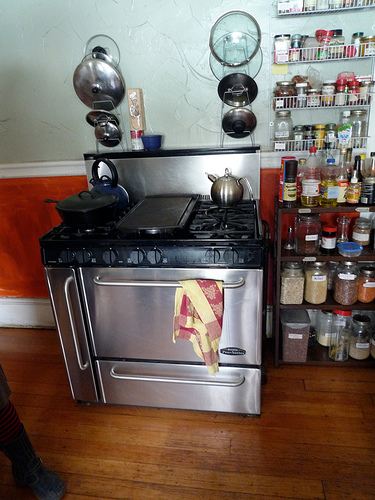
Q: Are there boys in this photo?
A: No, there are no boys.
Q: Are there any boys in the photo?
A: No, there are no boys.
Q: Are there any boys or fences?
A: No, there are no boys or fences.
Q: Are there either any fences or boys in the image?
A: No, there are no boys or fences.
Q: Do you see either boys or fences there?
A: No, there are no boys or fences.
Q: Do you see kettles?
A: Yes, there is a kettle.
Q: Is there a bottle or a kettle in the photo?
A: Yes, there is a kettle.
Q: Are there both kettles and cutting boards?
A: No, there is a kettle but no cutting boards.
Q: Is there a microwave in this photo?
A: No, there are no microwaves.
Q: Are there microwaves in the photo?
A: No, there are no microwaves.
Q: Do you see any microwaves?
A: No, there are no microwaves.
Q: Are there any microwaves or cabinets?
A: No, there are no microwaves or cabinets.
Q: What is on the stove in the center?
A: The kettle is on the stove.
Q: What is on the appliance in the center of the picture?
A: The kettle is on the stove.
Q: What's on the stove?
A: The kettle is on the stove.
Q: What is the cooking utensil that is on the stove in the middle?
A: The cooking utensil is a kettle.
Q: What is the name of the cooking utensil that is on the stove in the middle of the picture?
A: The cooking utensil is a kettle.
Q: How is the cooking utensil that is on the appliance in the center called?
A: The cooking utensil is a kettle.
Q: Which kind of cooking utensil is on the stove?
A: The cooking utensil is a kettle.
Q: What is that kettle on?
A: The kettle is on the stove.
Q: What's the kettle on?
A: The kettle is on the stove.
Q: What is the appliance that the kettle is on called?
A: The appliance is a stove.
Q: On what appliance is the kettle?
A: The kettle is on the stove.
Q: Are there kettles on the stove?
A: Yes, there is a kettle on the stove.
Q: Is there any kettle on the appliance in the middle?
A: Yes, there is a kettle on the stove.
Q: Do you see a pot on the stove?
A: No, there is a kettle on the stove.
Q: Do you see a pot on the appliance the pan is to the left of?
A: No, there is a kettle on the stove.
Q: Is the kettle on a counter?
A: No, the kettle is on the stove.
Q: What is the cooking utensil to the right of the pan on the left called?
A: The cooking utensil is a kettle.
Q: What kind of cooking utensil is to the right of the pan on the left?
A: The cooking utensil is a kettle.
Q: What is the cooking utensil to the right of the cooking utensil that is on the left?
A: The cooking utensil is a kettle.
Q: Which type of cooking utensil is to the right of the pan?
A: The cooking utensil is a kettle.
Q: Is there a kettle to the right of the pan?
A: Yes, there is a kettle to the right of the pan.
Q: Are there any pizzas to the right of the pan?
A: No, there is a kettle to the right of the pan.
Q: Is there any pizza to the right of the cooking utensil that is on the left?
A: No, there is a kettle to the right of the pan.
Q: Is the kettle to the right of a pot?
A: No, the kettle is to the right of a pan.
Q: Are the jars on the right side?
A: Yes, the jars are on the right of the image.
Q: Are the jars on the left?
A: No, the jars are on the right of the image.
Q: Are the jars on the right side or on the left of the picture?
A: The jars are on the right of the image.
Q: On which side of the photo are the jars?
A: The jars are on the right of the image.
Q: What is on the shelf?
A: The jars are on the shelf.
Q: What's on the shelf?
A: The jars are on the shelf.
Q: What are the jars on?
A: The jars are on the shelf.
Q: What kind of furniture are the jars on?
A: The jars are on the shelf.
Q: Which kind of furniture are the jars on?
A: The jars are on the shelf.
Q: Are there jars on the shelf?
A: Yes, there are jars on the shelf.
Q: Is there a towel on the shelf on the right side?
A: No, there are jars on the shelf.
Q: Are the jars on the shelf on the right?
A: Yes, the jars are on the shelf.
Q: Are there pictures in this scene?
A: No, there are no pictures.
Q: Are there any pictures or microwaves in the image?
A: No, there are no pictures or microwaves.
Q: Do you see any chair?
A: No, there are no chairs.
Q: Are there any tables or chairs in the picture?
A: No, there are no chairs or tables.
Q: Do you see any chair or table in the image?
A: No, there are no chairs or tables.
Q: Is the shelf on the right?
A: Yes, the shelf is on the right of the image.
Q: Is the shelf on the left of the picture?
A: No, the shelf is on the right of the image.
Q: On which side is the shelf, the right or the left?
A: The shelf is on the right of the image.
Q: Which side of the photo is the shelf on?
A: The shelf is on the right of the image.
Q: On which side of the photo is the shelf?
A: The shelf is on the right of the image.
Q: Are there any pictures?
A: No, there are no pictures.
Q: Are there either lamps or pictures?
A: No, there are no pictures or lamps.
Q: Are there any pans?
A: Yes, there is a pan.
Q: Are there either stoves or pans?
A: Yes, there is a pan.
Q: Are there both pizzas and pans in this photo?
A: No, there is a pan but no pizzas.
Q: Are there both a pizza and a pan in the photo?
A: No, there is a pan but no pizzas.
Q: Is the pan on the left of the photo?
A: Yes, the pan is on the left of the image.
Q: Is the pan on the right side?
A: No, the pan is on the left of the image.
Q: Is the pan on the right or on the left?
A: The pan is on the left of the image.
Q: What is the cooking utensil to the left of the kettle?
A: The cooking utensil is a pan.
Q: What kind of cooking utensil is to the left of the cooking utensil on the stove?
A: The cooking utensil is a pan.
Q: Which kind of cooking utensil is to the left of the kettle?
A: The cooking utensil is a pan.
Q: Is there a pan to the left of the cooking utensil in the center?
A: Yes, there is a pan to the left of the kettle.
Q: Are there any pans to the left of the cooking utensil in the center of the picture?
A: Yes, there is a pan to the left of the kettle.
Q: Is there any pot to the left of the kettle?
A: No, there is a pan to the left of the kettle.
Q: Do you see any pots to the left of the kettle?
A: No, there is a pan to the left of the kettle.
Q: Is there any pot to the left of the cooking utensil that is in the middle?
A: No, there is a pan to the left of the kettle.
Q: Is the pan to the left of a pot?
A: No, the pan is to the left of a kettle.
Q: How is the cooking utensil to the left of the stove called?
A: The cooking utensil is a pan.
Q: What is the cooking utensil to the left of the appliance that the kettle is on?
A: The cooking utensil is a pan.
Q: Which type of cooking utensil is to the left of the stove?
A: The cooking utensil is a pan.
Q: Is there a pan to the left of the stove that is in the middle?
A: Yes, there is a pan to the left of the stove.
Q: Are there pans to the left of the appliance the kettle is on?
A: Yes, there is a pan to the left of the stove.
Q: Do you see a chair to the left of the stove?
A: No, there is a pan to the left of the stove.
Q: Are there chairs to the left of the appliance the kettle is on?
A: No, there is a pan to the left of the stove.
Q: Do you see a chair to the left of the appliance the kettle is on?
A: No, there is a pan to the left of the stove.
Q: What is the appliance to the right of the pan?
A: The appliance is a stove.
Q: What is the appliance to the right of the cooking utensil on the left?
A: The appliance is a stove.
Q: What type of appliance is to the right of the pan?
A: The appliance is a stove.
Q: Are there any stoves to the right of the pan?
A: Yes, there is a stove to the right of the pan.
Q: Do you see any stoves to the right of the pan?
A: Yes, there is a stove to the right of the pan.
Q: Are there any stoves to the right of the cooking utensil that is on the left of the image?
A: Yes, there is a stove to the right of the pan.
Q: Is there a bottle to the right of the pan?
A: No, there is a stove to the right of the pan.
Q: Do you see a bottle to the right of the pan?
A: No, there is a stove to the right of the pan.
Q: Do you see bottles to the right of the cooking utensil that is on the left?
A: No, there is a stove to the right of the pan.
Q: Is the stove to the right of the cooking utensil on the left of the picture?
A: Yes, the stove is to the right of the pan.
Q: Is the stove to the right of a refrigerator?
A: No, the stove is to the right of the pan.